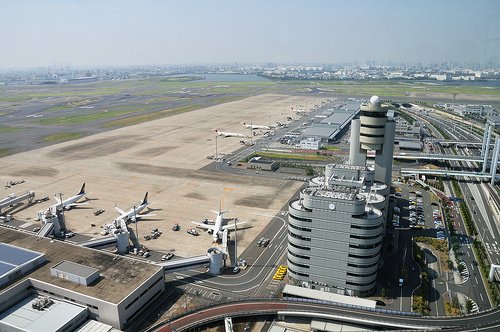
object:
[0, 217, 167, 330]
building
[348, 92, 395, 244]
building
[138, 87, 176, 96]
grass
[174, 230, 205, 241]
runway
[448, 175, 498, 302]
runway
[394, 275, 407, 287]
truck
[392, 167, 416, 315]
road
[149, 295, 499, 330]
road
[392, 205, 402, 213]
cars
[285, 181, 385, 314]
building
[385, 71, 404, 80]
buildings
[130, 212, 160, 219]
wing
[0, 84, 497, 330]
airport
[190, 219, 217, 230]
wing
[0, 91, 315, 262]
runway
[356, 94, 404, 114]
object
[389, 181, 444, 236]
parking lot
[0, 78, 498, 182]
ground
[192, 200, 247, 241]
airplane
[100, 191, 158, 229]
airplane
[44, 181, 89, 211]
airplane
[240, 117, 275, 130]
airplane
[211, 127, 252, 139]
airplane